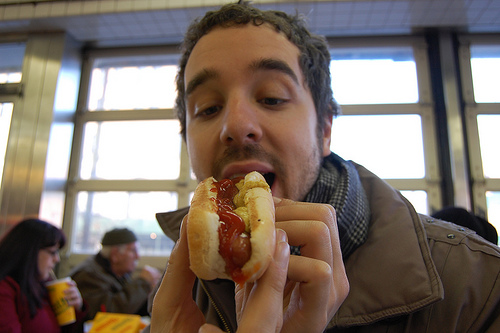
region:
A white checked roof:
[86, 7, 173, 42]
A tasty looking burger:
[183, 170, 275, 289]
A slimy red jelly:
[216, 175, 253, 287]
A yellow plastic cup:
[43, 274, 78, 328]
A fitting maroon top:
[3, 285, 49, 326]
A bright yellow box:
[85, 301, 145, 331]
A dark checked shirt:
[340, 168, 372, 228]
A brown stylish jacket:
[373, 208, 493, 326]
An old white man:
[95, 220, 144, 277]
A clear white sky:
[369, 135, 414, 172]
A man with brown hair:
[175, 3, 339, 198]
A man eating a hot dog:
[173, 8, 335, 280]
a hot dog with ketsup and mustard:
[183, 172, 276, 281]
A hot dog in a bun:
[186, 172, 273, 285]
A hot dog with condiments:
[186, 170, 276, 280]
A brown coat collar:
[354, 160, 445, 325]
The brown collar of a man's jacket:
[353, 159, 445, 324]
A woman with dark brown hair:
[2, 214, 67, 331]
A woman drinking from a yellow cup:
[43, 223, 80, 327]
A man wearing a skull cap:
[98, 228, 143, 279]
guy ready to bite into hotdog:
[150, 12, 375, 332]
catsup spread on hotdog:
[192, 165, 251, 281]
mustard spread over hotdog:
[216, 162, 276, 268]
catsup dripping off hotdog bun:
[192, 210, 274, 292]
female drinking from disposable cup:
[8, 222, 91, 330]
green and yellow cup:
[30, 256, 102, 331]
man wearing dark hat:
[67, 190, 187, 330]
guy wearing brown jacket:
[143, 11, 495, 317]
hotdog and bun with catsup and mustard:
[178, 161, 305, 298]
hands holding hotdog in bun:
[122, 172, 410, 329]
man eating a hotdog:
[163, 6, 497, 330]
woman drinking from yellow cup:
[3, 212, 91, 331]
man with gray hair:
[70, 214, 155, 297]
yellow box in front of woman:
[87, 314, 148, 331]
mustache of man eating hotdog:
[210, 136, 277, 187]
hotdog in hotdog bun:
[180, 169, 273, 270]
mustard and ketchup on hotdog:
[215, 170, 256, 227]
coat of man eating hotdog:
[170, 157, 498, 305]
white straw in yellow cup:
[49, 266, 59, 281]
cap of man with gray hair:
[99, 228, 135, 243]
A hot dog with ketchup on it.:
[186, 171, 280, 284]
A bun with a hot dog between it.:
[186, 169, 275, 284]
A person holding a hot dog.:
[135, 3, 496, 326]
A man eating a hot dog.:
[146, 1, 497, 324]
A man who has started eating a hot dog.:
[147, 0, 493, 327]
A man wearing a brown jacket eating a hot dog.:
[150, 4, 492, 327]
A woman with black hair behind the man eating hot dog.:
[0, 216, 87, 327]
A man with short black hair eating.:
[147, 5, 494, 331]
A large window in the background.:
[32, 32, 442, 270]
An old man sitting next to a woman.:
[60, 226, 157, 324]